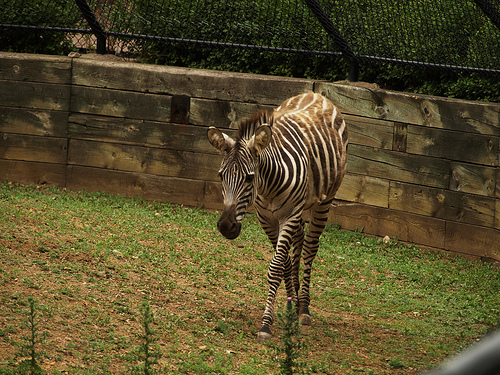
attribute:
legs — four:
[255, 207, 334, 335]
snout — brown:
[215, 203, 243, 240]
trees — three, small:
[23, 289, 301, 372]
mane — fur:
[226, 114, 269, 165]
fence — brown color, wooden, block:
[1, 50, 484, 250]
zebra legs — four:
[246, 200, 326, 342]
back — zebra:
[266, 90, 318, 139]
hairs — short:
[260, 112, 298, 119]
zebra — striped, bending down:
[204, 92, 353, 338]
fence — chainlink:
[4, 2, 484, 78]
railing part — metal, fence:
[433, 331, 484, 372]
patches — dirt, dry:
[16, 227, 188, 306]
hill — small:
[1, 184, 204, 364]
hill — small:
[0, 181, 401, 372]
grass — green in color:
[406, 254, 479, 324]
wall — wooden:
[1, 49, 484, 245]